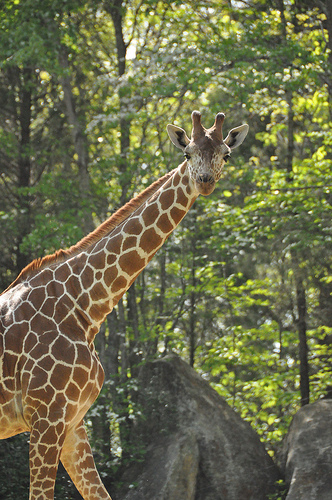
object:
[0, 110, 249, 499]
giraffe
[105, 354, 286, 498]
boulder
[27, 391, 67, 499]
front legs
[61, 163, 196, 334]
neck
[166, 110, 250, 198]
head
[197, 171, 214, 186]
nose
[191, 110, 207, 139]
horns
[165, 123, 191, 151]
ears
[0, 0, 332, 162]
sky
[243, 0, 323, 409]
trees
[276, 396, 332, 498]
boulder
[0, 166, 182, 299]
mane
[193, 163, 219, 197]
muzzle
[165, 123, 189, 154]
right ear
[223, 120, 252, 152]
left ear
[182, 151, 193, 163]
eyes